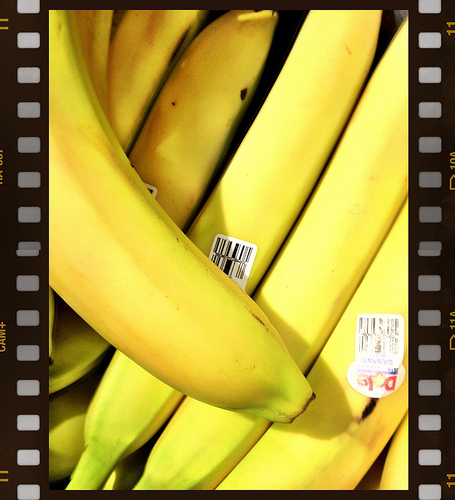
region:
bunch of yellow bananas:
[50, 12, 398, 485]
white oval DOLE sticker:
[343, 351, 405, 402]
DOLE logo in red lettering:
[337, 353, 407, 395]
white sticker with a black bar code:
[203, 229, 264, 287]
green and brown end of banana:
[256, 366, 319, 425]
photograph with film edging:
[4, 8, 453, 495]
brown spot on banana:
[217, 76, 260, 120]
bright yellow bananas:
[53, 18, 391, 470]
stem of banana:
[61, 434, 117, 491]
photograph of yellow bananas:
[52, 21, 405, 479]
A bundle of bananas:
[42, 11, 407, 486]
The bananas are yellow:
[48, 12, 405, 488]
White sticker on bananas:
[349, 317, 407, 397]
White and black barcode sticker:
[205, 233, 260, 289]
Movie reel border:
[3, 0, 452, 491]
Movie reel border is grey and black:
[8, 9, 450, 495]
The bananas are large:
[51, 12, 406, 484]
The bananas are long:
[52, 31, 406, 488]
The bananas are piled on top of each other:
[47, 12, 406, 494]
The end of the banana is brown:
[270, 380, 323, 429]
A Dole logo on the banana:
[355, 371, 399, 390]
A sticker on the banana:
[208, 235, 252, 286]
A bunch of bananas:
[48, 8, 408, 488]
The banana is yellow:
[49, 10, 314, 422]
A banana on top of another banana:
[49, 10, 315, 423]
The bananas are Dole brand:
[50, 9, 407, 488]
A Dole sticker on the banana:
[351, 314, 404, 397]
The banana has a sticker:
[218, 203, 409, 489]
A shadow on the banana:
[263, 309, 351, 435]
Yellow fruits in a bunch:
[47, 11, 407, 489]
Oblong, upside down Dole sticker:
[346, 359, 407, 397]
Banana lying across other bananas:
[47, 8, 315, 426]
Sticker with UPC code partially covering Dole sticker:
[355, 313, 405, 368]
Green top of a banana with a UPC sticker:
[66, 353, 183, 498]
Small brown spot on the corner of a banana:
[236, 84, 249, 101]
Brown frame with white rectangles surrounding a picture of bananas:
[2, 1, 453, 498]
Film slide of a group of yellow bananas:
[0, 0, 454, 497]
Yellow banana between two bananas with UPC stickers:
[131, 9, 407, 488]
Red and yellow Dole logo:
[353, 370, 397, 392]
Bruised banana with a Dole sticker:
[214, 202, 408, 489]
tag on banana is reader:
[209, 222, 264, 299]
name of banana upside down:
[347, 361, 397, 409]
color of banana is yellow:
[73, 237, 297, 412]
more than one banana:
[117, 237, 364, 484]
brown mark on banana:
[211, 78, 276, 118]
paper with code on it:
[349, 312, 405, 374]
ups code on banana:
[208, 242, 242, 294]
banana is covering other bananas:
[66, 106, 318, 432]